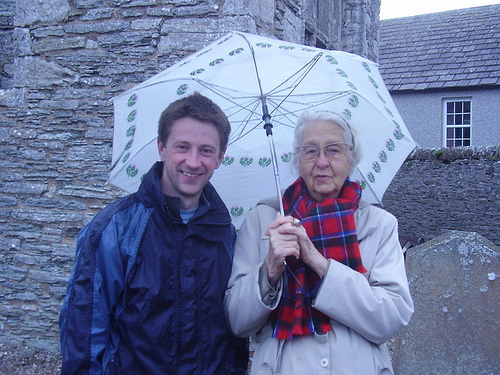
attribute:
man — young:
[58, 90, 251, 375]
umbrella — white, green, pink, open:
[104, 30, 418, 233]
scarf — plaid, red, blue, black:
[268, 176, 367, 340]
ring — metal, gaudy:
[293, 218, 302, 227]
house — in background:
[376, 2, 499, 154]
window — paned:
[440, 95, 473, 147]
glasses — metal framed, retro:
[293, 141, 348, 162]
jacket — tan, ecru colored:
[221, 197, 415, 374]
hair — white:
[293, 107, 363, 173]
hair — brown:
[155, 87, 232, 158]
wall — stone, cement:
[380, 227, 499, 374]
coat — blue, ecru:
[58, 161, 251, 374]